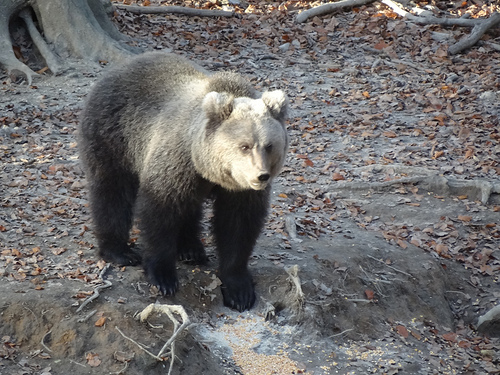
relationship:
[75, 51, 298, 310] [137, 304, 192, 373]
bear behind stick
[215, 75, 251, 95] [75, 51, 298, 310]
fur on bear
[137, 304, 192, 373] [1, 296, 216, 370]
stick on ground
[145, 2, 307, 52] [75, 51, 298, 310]
leaves are below bear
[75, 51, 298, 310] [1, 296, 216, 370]
bear on ground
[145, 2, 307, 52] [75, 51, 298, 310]
leaves are  behind bear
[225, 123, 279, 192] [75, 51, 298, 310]
face on bear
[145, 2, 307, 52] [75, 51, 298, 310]
leaves are behind bear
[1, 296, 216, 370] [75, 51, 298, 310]
ground beneath bear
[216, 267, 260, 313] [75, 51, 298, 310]
paw on bear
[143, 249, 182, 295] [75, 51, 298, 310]
paw on bear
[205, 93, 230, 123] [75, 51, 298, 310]
ear on bear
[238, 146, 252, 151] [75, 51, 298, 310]
eye on bear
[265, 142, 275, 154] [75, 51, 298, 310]
eye on bear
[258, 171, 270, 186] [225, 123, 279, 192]
nose on face